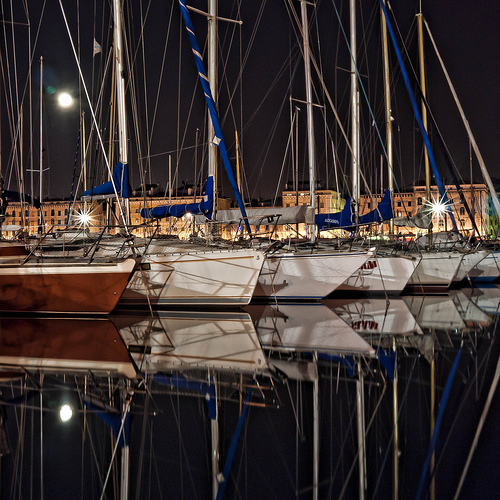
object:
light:
[53, 86, 72, 109]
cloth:
[142, 176, 214, 221]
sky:
[0, 0, 500, 206]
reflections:
[0, 282, 500, 499]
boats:
[0, 0, 136, 318]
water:
[3, 285, 498, 498]